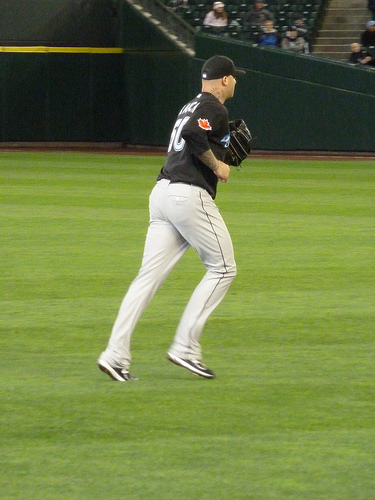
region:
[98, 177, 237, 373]
a pair of white pants.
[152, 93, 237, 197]
a black t shirt.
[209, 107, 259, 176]
a glove on a man's hand.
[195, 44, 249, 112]
a man wearing a hat.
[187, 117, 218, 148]
a tag on a man's shirt.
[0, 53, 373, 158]
a wall near a stadium.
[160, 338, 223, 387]
a right foot shoe.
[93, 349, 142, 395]
a left foot shoe.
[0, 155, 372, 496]
A field of green grass.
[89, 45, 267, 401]
there is a man on the playing field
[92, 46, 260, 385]
the man is playing baseball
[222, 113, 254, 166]
the mans mitt is black in color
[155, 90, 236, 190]
the mans jersey is black in color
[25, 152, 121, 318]
the playing field is made up of green grass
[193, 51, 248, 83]
the man is wearing a baseball cap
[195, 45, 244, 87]
the baseball cap is black in color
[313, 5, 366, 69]
there are stairs in the staduim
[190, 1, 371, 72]
these people are watching the baseball game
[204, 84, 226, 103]
the man has a tattoo on his neck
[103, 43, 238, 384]
baseball player running on field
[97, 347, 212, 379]
black and white cleats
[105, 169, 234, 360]
pants of baseball player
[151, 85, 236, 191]
black jersey of baseball player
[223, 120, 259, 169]
black glove of baseball player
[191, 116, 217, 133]
red patch on black sleeve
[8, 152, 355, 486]
field player is running on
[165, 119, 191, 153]
white numbers on black jersey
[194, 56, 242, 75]
black hat of player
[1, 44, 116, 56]
yellow line painted on wall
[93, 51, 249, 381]
A baseball player jogging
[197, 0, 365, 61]
Spectators watching a baseball game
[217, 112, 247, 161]
A black baseball glove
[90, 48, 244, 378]
A baseball player running to make a play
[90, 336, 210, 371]
Baseball player's feet in motion to make a catch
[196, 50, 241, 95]
Baseball player wearing a black cap on his head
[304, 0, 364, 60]
Staircase leading down to spectator seats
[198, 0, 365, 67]
Baseball fans enjoying a game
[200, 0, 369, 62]
Baseball fans dressed warmly for a chilly day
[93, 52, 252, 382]
Toronto Blue Jays player jogging to make a catch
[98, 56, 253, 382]
ballplayer jogging to the dugout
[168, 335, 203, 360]
bottom of pants bunched up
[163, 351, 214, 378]
baseball cleats on player's foot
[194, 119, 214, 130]
patch on the sleeve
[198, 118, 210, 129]
patch on the sleeve of a player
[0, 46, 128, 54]
a line for marking home runs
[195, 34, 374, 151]
padding on the wall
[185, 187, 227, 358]
stripe on the pants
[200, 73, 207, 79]
logo on the back of a cap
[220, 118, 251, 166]
black baseball glove on left hand